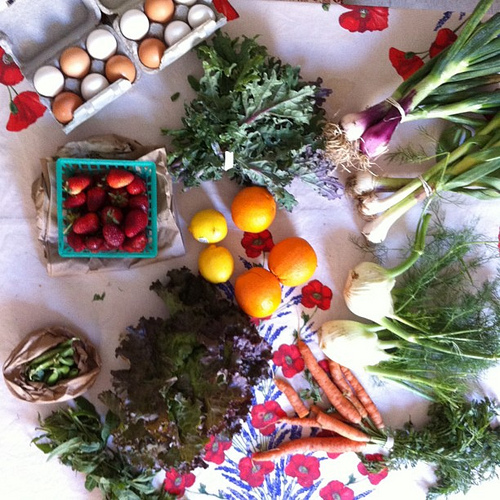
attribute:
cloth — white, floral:
[1, 5, 500, 479]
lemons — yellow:
[192, 212, 231, 285]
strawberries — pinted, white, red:
[62, 169, 152, 254]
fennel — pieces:
[308, 209, 499, 407]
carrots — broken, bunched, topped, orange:
[241, 335, 494, 488]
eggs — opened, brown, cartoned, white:
[2, 1, 217, 140]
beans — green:
[26, 355, 87, 384]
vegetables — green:
[181, 42, 316, 195]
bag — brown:
[12, 335, 102, 401]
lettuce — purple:
[102, 268, 269, 469]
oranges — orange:
[230, 189, 315, 321]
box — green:
[48, 158, 164, 268]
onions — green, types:
[363, 100, 495, 249]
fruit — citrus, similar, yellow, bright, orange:
[183, 187, 322, 326]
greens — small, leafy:
[176, 30, 326, 195]